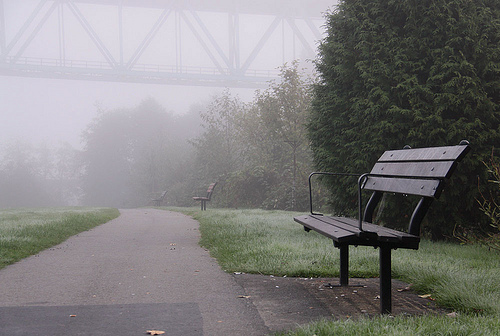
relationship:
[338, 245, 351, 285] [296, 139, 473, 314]
leg of bench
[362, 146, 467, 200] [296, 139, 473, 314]
backplate of bench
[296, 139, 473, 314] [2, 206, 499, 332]
bench in ground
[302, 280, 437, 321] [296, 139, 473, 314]
brick under bench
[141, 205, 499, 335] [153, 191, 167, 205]
grass under bench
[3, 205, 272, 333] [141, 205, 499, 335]
road next to grass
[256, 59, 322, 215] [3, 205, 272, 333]
tree next to road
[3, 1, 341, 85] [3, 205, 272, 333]
bridge over road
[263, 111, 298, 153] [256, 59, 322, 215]
branch on tree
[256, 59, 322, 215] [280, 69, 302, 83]
tree has leaves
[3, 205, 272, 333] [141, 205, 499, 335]
walkway next to grass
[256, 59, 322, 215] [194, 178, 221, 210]
tree behind bench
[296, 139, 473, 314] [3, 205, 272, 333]
bench next to pathway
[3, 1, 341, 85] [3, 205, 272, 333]
bridge over pathway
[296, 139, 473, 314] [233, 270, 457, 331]
bench in cement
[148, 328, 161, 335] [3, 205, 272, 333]
leaf on asphalt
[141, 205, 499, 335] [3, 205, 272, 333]
grass next to walkway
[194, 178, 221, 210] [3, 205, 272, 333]
bench next to walkway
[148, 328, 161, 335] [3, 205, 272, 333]
leaf on walkway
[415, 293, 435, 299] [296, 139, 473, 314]
leaf beneath bench